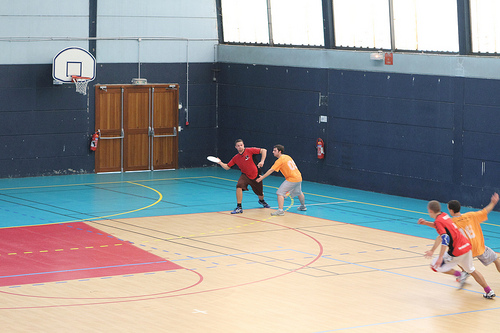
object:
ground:
[0, 168, 500, 333]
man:
[215, 138, 271, 214]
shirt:
[447, 209, 487, 258]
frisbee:
[206, 156, 221, 163]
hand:
[215, 156, 222, 165]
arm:
[434, 221, 450, 258]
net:
[71, 78, 90, 96]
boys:
[419, 199, 500, 300]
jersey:
[227, 147, 260, 181]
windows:
[455, 0, 500, 55]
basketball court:
[0, 166, 500, 333]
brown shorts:
[237, 173, 264, 197]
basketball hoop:
[69, 75, 92, 96]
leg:
[276, 180, 295, 210]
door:
[93, 83, 180, 173]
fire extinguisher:
[89, 131, 101, 152]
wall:
[215, 62, 499, 211]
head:
[234, 137, 246, 152]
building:
[0, 0, 500, 333]